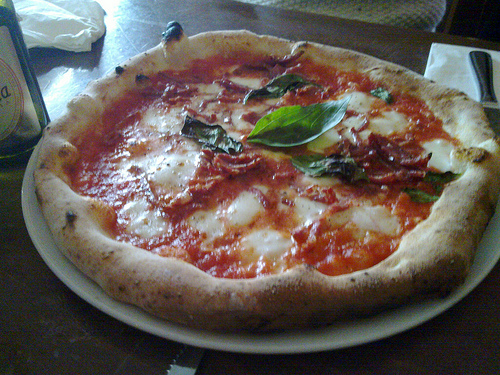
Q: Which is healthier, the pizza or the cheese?
A: The cheese is healthier than the pizza.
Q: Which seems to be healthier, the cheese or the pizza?
A: The cheese is healthier than the pizza.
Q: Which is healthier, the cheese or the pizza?
A: The cheese is healthier than the pizza.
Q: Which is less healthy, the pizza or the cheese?
A: The pizza is less healthy than the cheese.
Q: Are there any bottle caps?
A: No, there are no bottle caps.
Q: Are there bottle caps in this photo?
A: No, there are no bottle caps.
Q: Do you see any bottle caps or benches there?
A: No, there are no bottle caps or benches.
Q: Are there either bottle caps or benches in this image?
A: No, there are no bottle caps or benches.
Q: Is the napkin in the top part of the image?
A: Yes, the napkin is in the top of the image.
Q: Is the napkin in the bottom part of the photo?
A: No, the napkin is in the top of the image.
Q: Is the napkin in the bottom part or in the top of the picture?
A: The napkin is in the top of the image.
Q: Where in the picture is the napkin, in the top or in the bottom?
A: The napkin is in the top of the image.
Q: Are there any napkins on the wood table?
A: Yes, there is a napkin on the table.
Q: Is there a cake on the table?
A: No, there is a napkin on the table.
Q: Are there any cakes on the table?
A: No, there is a napkin on the table.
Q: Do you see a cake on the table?
A: No, there is a napkin on the table.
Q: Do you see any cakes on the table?
A: No, there is a napkin on the table.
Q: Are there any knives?
A: Yes, there is a knife.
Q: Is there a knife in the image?
A: Yes, there is a knife.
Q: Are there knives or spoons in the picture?
A: Yes, there is a knife.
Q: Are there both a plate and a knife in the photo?
A: Yes, there are both a knife and a plate.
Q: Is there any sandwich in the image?
A: No, there are no sandwiches.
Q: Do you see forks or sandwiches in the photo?
A: No, there are no sandwiches or forks.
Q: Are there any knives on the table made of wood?
A: Yes, there is a knife on the table.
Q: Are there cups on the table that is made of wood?
A: No, there is a knife on the table.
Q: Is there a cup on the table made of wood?
A: No, there is a knife on the table.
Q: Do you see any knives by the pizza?
A: Yes, there is a knife by the pizza.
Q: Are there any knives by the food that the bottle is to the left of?
A: Yes, there is a knife by the pizza.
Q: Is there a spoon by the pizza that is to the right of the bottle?
A: No, there is a knife by the pizza.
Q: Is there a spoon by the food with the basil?
A: No, there is a knife by the pizza.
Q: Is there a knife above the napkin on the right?
A: Yes, there is a knife above the napkin.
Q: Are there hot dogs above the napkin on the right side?
A: No, there is a knife above the napkin.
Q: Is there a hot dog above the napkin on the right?
A: No, there is a knife above the napkin.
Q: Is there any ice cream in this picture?
A: No, there is no ice cream.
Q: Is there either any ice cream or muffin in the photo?
A: No, there are no ice cream or muffins.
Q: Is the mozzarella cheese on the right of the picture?
A: Yes, the mozzarella cheese is on the right of the image.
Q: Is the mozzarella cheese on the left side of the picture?
A: No, the mozzarella cheese is on the right of the image.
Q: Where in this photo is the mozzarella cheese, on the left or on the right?
A: The mozzarella cheese is on the right of the image.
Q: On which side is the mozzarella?
A: The mozzarella is on the right of the image.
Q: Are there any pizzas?
A: Yes, there is a pizza.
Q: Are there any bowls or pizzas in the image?
A: Yes, there is a pizza.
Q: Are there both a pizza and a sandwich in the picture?
A: No, there is a pizza but no sandwiches.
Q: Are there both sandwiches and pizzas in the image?
A: No, there is a pizza but no sandwiches.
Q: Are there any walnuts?
A: No, there are no walnuts.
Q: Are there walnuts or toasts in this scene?
A: No, there are no walnuts or toasts.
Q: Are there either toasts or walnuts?
A: No, there are no walnuts or toasts.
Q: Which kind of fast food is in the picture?
A: The fast food is a pizza.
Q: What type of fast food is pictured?
A: The fast food is a pizza.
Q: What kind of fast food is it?
A: The food is a pizza.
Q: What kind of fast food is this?
A: This is a pizza.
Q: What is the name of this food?
A: This is a pizza.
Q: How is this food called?
A: This is a pizza.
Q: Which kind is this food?
A: This is a pizza.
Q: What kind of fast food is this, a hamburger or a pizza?
A: This is a pizza.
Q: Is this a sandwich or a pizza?
A: This is a pizza.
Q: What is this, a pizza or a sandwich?
A: This is a pizza.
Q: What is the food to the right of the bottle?
A: The food is a pizza.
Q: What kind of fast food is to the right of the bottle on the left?
A: The food is a pizza.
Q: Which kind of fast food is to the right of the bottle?
A: The food is a pizza.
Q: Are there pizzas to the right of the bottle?
A: Yes, there is a pizza to the right of the bottle.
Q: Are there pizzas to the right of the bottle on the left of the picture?
A: Yes, there is a pizza to the right of the bottle.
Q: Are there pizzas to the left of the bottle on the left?
A: No, the pizza is to the right of the bottle.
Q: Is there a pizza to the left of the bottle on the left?
A: No, the pizza is to the right of the bottle.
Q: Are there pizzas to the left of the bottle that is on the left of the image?
A: No, the pizza is to the right of the bottle.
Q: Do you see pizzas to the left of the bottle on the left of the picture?
A: No, the pizza is to the right of the bottle.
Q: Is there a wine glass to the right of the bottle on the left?
A: No, there is a pizza to the right of the bottle.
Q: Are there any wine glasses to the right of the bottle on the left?
A: No, there is a pizza to the right of the bottle.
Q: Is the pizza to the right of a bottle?
A: Yes, the pizza is to the right of a bottle.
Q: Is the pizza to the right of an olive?
A: No, the pizza is to the right of a bottle.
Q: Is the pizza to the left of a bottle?
A: No, the pizza is to the right of a bottle.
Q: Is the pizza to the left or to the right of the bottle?
A: The pizza is to the right of the bottle.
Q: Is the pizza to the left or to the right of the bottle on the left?
A: The pizza is to the right of the bottle.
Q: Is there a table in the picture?
A: Yes, there is a table.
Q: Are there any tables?
A: Yes, there is a table.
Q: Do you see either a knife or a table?
A: Yes, there is a table.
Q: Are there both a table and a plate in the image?
A: Yes, there are both a table and a plate.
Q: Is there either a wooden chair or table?
A: Yes, there is a wood table.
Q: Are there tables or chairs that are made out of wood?
A: Yes, the table is made of wood.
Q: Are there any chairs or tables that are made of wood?
A: Yes, the table is made of wood.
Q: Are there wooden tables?
A: Yes, there is a wood table.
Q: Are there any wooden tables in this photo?
A: Yes, there is a wood table.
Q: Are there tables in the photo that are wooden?
A: Yes, there is a table that is wooden.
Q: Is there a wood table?
A: Yes, there is a table that is made of wood.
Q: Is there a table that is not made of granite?
A: Yes, there is a table that is made of wood.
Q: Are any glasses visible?
A: No, there are no glasses.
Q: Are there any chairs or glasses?
A: No, there are no glasses or chairs.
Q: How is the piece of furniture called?
A: The piece of furniture is a table.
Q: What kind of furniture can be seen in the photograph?
A: The furniture is a table.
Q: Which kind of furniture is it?
A: The piece of furniture is a table.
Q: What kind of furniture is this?
A: This is a table.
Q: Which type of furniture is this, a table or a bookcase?
A: This is a table.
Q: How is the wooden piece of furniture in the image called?
A: The piece of furniture is a table.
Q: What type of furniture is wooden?
A: The furniture is a table.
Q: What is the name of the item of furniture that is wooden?
A: The piece of furniture is a table.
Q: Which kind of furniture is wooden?
A: The furniture is a table.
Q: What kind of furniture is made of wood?
A: The furniture is a table.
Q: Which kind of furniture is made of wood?
A: The furniture is a table.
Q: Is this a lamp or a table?
A: This is a table.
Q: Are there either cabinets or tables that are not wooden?
A: No, there is a table but it is wooden.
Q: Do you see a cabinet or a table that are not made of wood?
A: No, there is a table but it is made of wood.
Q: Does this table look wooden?
A: Yes, the table is wooden.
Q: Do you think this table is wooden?
A: Yes, the table is wooden.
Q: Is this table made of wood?
A: Yes, the table is made of wood.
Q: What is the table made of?
A: The table is made of wood.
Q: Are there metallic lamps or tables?
A: No, there is a table but it is wooden.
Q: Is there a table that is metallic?
A: No, there is a table but it is wooden.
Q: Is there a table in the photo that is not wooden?
A: No, there is a table but it is wooden.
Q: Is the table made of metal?
A: No, the table is made of wood.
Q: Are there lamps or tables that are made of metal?
A: No, there is a table but it is made of wood.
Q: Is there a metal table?
A: No, there is a table but it is made of wood.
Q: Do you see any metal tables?
A: No, there is a table but it is made of wood.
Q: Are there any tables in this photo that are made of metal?
A: No, there is a table but it is made of wood.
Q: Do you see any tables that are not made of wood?
A: No, there is a table but it is made of wood.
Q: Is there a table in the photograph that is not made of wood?
A: No, there is a table but it is made of wood.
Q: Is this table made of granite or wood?
A: The table is made of wood.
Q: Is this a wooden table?
A: Yes, this is a wooden table.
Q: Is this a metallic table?
A: No, this is a wooden table.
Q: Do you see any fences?
A: No, there are no fences.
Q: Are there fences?
A: No, there are no fences.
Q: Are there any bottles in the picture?
A: Yes, there is a bottle.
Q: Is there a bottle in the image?
A: Yes, there is a bottle.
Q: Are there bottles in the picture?
A: Yes, there is a bottle.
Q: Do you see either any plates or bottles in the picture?
A: Yes, there is a bottle.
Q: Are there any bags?
A: No, there are no bags.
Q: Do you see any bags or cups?
A: No, there are no bags or cups.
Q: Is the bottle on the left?
A: Yes, the bottle is on the left of the image.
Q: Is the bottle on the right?
A: No, the bottle is on the left of the image.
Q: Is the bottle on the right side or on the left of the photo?
A: The bottle is on the left of the image.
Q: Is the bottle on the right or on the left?
A: The bottle is on the left of the image.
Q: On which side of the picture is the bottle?
A: The bottle is on the left of the image.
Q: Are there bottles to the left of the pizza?
A: Yes, there is a bottle to the left of the pizza.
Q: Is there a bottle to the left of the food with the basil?
A: Yes, there is a bottle to the left of the pizza.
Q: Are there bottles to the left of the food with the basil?
A: Yes, there is a bottle to the left of the pizza.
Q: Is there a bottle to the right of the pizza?
A: No, the bottle is to the left of the pizza.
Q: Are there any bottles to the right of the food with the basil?
A: No, the bottle is to the left of the pizza.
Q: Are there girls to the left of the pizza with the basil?
A: No, there is a bottle to the left of the pizza.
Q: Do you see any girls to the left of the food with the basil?
A: No, there is a bottle to the left of the pizza.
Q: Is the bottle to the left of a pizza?
A: Yes, the bottle is to the left of a pizza.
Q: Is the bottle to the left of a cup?
A: No, the bottle is to the left of a pizza.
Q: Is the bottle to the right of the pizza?
A: No, the bottle is to the left of the pizza.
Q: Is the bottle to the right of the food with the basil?
A: No, the bottle is to the left of the pizza.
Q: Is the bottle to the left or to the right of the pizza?
A: The bottle is to the left of the pizza.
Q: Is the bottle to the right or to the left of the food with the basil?
A: The bottle is to the left of the pizza.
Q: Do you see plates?
A: Yes, there is a plate.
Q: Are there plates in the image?
A: Yes, there is a plate.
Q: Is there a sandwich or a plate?
A: Yes, there is a plate.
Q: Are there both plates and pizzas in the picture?
A: Yes, there are both a plate and a pizza.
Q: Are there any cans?
A: No, there are no cans.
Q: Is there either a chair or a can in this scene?
A: No, there are no cans or chairs.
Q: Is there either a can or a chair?
A: No, there are no cans or chairs.